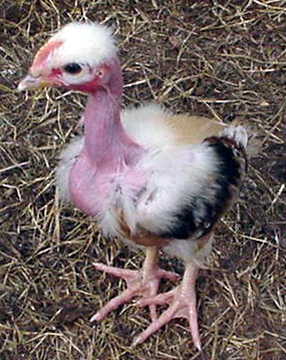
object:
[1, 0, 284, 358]
dirt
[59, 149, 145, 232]
bird breast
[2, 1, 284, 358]
grass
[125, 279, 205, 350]
foot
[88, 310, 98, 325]
nail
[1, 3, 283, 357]
ground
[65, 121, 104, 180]
fur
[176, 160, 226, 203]
fur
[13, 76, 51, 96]
beak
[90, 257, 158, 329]
feet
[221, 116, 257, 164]
tail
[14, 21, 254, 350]
baby turkey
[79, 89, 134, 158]
neck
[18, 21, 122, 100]
head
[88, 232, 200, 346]
legs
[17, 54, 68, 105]
peak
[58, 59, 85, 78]
eye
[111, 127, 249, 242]
feathers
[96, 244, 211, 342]
talon